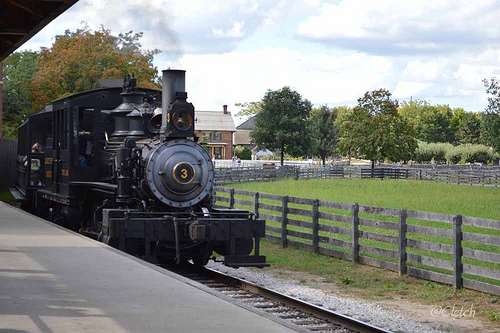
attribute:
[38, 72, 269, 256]
train — big, traveling, moving, here, close, old, black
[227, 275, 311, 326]
tracks — below, black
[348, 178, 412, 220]
grass — here, close, below, lush, wild, bushy, thick, green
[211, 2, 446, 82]
sky — cloudy, overcast, blue, white, above, high, close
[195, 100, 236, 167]
house — red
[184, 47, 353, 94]
clouds — white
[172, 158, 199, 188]
3 — yellow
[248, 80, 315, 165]
tree — large, green